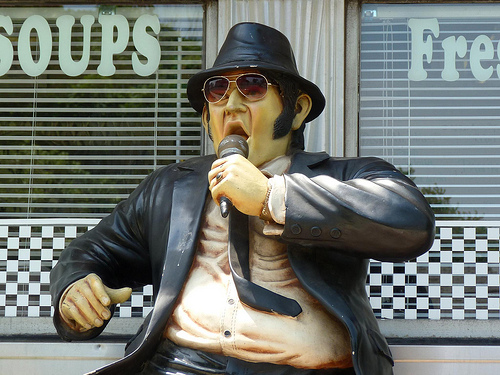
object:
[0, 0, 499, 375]
picture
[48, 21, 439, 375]
statue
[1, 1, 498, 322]
restaraunt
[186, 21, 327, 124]
hat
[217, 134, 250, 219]
microphone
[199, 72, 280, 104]
sunglasses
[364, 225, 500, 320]
tiles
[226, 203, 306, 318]
tie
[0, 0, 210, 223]
window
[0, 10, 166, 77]
words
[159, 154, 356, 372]
shirt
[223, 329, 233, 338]
button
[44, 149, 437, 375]
jacket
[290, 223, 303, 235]
button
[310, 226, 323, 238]
button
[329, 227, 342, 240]
button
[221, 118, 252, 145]
mouth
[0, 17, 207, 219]
blinds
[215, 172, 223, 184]
ring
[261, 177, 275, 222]
watch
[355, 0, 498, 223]
window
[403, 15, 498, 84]
words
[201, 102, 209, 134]
ear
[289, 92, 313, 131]
ear